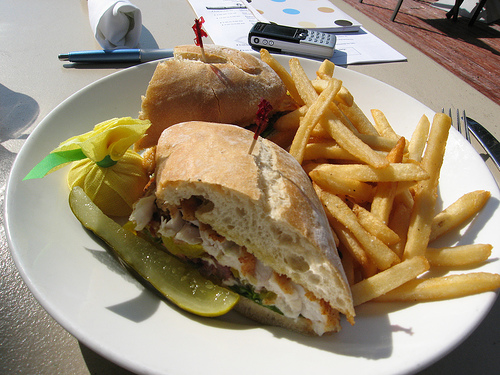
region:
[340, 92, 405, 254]
French fries on plate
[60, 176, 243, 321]
Cut pickle on plate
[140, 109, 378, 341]
Half a sandwich on plate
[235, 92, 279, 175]
Tooth pick in sandwich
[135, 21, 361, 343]
Two sandwiches on plate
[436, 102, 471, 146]
The prongs of a fork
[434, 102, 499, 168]
Fork and knife next to plate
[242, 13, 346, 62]
Mobile phone on table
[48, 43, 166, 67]
Ink pen on table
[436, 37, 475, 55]
Wooden Floor under a table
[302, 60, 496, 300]
fries on a plate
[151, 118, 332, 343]
a sandwich on a plate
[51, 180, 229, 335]
a pickle on a plate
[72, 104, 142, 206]
a yellow sack on a plate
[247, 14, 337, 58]
a phone on a desk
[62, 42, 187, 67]
a silver pen on the desk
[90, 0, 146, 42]
a napkin on a desk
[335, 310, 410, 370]
a shadow on a plate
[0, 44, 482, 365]
a plate full of food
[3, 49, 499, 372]
a round white plate with food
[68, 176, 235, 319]
A long green pickle spear.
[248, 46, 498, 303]
Golden french fries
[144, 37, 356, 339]
A sandwich cut in half.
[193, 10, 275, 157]
Toothpicks with red plastic on top.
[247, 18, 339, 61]
A black and grey cellphone.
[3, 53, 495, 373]
A round white plate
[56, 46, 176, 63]
A blue pen.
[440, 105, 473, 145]
A silver fork.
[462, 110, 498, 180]
A silver butter knife.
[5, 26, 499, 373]
A plate of food.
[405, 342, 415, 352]
part of a plate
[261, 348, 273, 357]
edge of a plate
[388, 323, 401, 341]
side of a plate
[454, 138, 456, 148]
part of a fork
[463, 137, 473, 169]
part of a knife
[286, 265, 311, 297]
part of a bread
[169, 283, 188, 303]
part of a cocktail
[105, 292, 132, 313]
edge of a plate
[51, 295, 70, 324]
side of a plate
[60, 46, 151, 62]
pen on the table.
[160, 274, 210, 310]
pickle on the plate.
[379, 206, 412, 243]
fries on the plate.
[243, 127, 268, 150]
toothpick in the bread.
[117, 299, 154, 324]
shadow on the plate.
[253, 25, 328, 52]
phone on the paper.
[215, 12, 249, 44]
paper on the table.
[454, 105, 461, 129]
thine of the fork.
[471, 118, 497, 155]
knife on the table.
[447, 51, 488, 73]
floor made of wood.